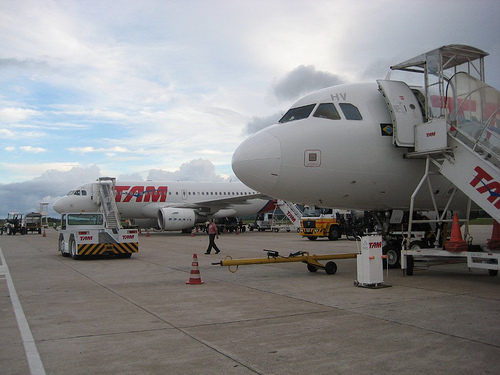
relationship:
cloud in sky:
[0, 0, 500, 216] [9, 2, 467, 235]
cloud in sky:
[0, 0, 500, 216] [10, 5, 436, 195]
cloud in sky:
[0, 0, 500, 216] [8, 6, 216, 151]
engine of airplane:
[156, 204, 198, 231] [51, 175, 301, 233]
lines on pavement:
[3, 252, 57, 372] [11, 228, 484, 372]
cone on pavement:
[186, 246, 203, 283] [0, 277, 496, 372]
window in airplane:
[339, 97, 367, 124] [233, 105, 403, 190]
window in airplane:
[316, 103, 341, 121] [233, 105, 403, 190]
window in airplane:
[278, 105, 316, 121] [233, 105, 403, 190]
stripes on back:
[75, 241, 139, 255] [70, 226, 138, 255]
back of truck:
[70, 226, 138, 255] [55, 209, 139, 259]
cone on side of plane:
[487, 217, 498, 254] [230, 77, 497, 224]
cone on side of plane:
[446, 215, 468, 253] [230, 77, 497, 224]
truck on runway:
[279, 213, 359, 248] [99, 221, 499, 348]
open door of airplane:
[89, 180, 99, 205] [51, 178, 345, 233]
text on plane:
[109, 179, 170, 208] [48, 164, 304, 244]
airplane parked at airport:
[233, 73, 499, 269] [26, 42, 474, 373]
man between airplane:
[202, 217, 221, 259] [233, 73, 499, 269]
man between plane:
[202, 217, 221, 259] [54, 179, 273, 239]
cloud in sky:
[0, 0, 500, 216] [4, 3, 498, 210]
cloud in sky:
[53, 95, 136, 127] [4, 3, 498, 210]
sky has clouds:
[4, 4, 229, 175] [138, 144, 228, 179]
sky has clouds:
[4, 4, 229, 175] [5, 49, 79, 121]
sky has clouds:
[4, 4, 229, 175] [248, 54, 337, 89]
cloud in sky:
[0, 0, 500, 216] [3, 10, 497, 227]